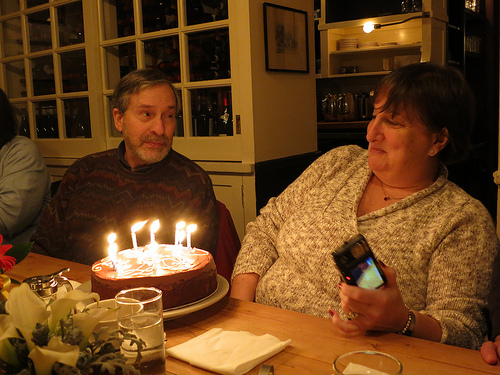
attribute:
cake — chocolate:
[87, 240, 220, 314]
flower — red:
[3, 229, 24, 299]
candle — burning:
[174, 231, 188, 267]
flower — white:
[13, 278, 90, 337]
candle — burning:
[87, 202, 207, 252]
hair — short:
[406, 66, 458, 113]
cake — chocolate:
[88, 217, 253, 312]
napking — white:
[167, 321, 301, 373]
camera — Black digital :
[328, 222, 395, 298]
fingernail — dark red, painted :
[327, 309, 334, 316]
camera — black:
[328, 223, 412, 297]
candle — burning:
[127, 217, 147, 249]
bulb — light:
[361, 20, 376, 35]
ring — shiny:
[346, 313, 354, 323]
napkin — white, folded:
[171, 315, 296, 373]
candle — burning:
[172, 216, 182, 245]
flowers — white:
[7, 253, 95, 283]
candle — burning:
[187, 221, 198, 251]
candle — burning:
[148, 217, 161, 246]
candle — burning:
[109, 242, 119, 269]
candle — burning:
[175, 230, 185, 252]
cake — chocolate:
[91, 243, 218, 310]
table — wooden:
[5, 249, 498, 371]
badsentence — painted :
[343, 288, 387, 316]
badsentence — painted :
[336, 320, 401, 346]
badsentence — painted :
[363, 287, 399, 322]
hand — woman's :
[343, 261, 408, 331]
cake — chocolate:
[86, 238, 230, 312]